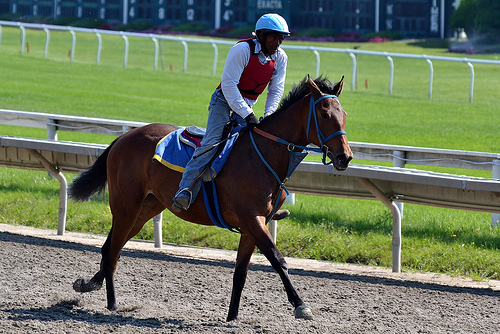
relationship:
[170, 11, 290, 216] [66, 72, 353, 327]
jockey riding horse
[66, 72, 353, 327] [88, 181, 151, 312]
horse has leg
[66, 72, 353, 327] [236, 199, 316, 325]
horse has front right leg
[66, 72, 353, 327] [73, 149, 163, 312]
horse has back two legs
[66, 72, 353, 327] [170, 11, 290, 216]
horse with jockey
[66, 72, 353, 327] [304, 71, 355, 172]
horse has head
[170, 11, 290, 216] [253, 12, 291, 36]
jockey has helmet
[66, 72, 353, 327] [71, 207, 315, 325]
horse has legs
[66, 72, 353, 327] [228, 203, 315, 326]
horse has front legs